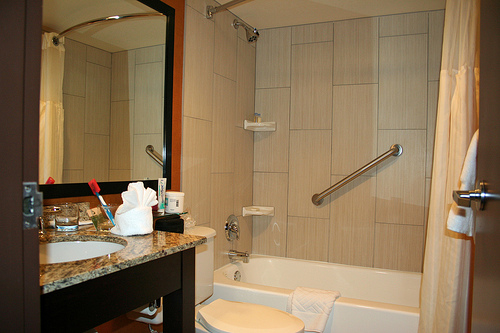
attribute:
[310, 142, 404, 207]
rail bar — metal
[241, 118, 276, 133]
shelf — white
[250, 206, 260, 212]
soap — bar, white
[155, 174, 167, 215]
toothpaste — tube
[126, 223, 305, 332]
toilet — beige, white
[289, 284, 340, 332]
towel — white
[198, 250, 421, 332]
bathtub — white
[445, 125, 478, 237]
towel — white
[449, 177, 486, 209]
door handle — chrome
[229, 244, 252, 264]
faucet — chrome, silver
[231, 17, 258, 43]
shower head — chrome, silver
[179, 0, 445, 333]
shower — wide open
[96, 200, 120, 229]
glass — empty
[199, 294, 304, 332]
seat — down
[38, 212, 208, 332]
vanity — granite topped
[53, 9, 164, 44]
curtain rod — curved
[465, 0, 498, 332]
door — brown